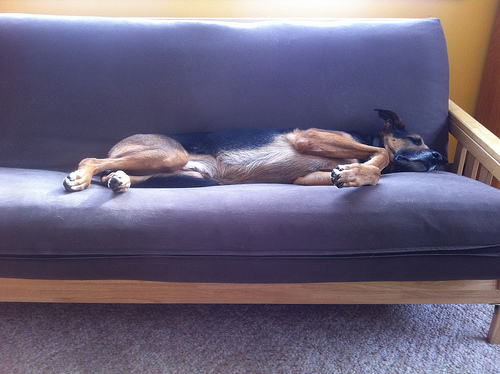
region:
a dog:
[38, 97, 450, 194]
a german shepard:
[59, 100, 444, 196]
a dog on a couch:
[54, 102, 454, 203]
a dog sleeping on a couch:
[55, 104, 457, 199]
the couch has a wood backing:
[1, 8, 497, 350]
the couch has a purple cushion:
[4, 8, 497, 287]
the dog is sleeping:
[46, 81, 461, 241]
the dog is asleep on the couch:
[67, 89, 473, 260]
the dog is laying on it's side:
[43, 89, 465, 206]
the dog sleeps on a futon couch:
[47, 75, 457, 242]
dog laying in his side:
[64, 103, 453, 204]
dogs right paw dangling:
[322, 158, 384, 190]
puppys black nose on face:
[426, 143, 445, 163]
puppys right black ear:
[365, 90, 405, 130]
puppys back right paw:
[64, 150, 103, 198]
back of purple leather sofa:
[27, 21, 444, 105]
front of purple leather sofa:
[17, 189, 464, 255]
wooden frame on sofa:
[20, 284, 474, 303]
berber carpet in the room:
[57, 320, 487, 371]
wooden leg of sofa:
[481, 311, 498, 343]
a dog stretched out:
[60, 106, 441, 201]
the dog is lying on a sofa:
[1, 9, 497, 302]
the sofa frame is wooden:
[0, 7, 497, 344]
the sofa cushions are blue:
[1, 9, 498, 287]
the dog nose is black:
[405, 147, 445, 170]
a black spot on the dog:
[150, 126, 284, 152]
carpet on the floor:
[2, 289, 499, 371]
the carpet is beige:
[2, 303, 494, 372]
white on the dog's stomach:
[217, 143, 299, 166]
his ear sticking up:
[365, 97, 408, 133]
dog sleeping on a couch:
[66, 93, 447, 203]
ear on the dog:
[372, 100, 407, 136]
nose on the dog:
[423, 143, 445, 179]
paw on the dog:
[57, 148, 88, 202]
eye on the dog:
[402, 125, 430, 149]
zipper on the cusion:
[306, 236, 498, 268]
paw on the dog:
[332, 159, 382, 194]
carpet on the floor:
[240, 328, 420, 373]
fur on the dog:
[222, 124, 287, 184]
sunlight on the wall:
[249, 3, 349, 18]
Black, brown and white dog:
[47, 83, 449, 200]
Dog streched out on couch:
[70, 92, 448, 215]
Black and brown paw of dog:
[323, 159, 362, 194]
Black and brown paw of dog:
[49, 166, 91, 193]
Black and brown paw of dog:
[106, 172, 143, 197]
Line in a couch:
[12, 225, 498, 283]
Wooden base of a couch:
[2, 273, 498, 312]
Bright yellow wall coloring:
[448, 14, 484, 83]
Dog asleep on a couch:
[4, 8, 498, 319]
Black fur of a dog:
[197, 126, 256, 148]